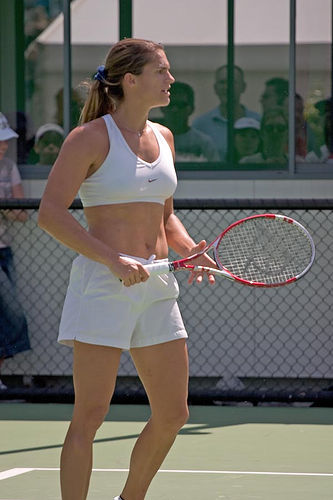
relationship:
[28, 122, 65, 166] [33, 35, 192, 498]
people watching watching match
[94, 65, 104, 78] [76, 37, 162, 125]
bow in hair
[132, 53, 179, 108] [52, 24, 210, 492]
face on girl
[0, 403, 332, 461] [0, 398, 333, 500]
shadow on court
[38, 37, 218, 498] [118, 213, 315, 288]
girl holding racket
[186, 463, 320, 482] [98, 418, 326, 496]
white line on court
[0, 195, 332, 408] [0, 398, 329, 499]
fence surrounding court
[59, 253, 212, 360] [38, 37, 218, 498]
shorts on girl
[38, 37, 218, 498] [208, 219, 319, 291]
girl holding racket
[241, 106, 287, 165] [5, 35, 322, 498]
people watching event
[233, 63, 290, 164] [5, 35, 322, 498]
people watching watching event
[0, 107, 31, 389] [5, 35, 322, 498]
people watching event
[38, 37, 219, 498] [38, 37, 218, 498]
girl play girl